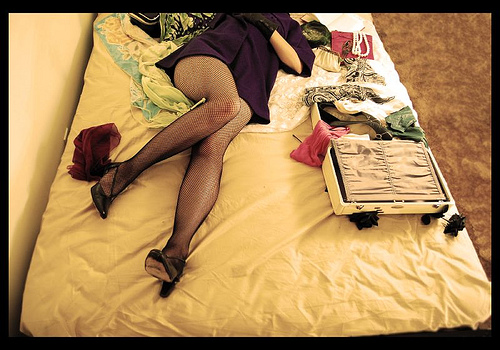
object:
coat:
[155, 12, 315, 125]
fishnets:
[101, 55, 253, 262]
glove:
[235, 13, 281, 39]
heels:
[143, 245, 193, 299]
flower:
[433, 214, 466, 238]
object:
[65, 119, 120, 182]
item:
[385, 105, 425, 144]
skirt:
[322, 100, 392, 141]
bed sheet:
[16, 8, 493, 336]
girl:
[89, 0, 317, 298]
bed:
[15, 11, 498, 344]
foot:
[144, 248, 189, 283]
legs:
[154, 94, 252, 247]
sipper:
[354, 28, 364, 55]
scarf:
[333, 30, 373, 59]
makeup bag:
[302, 43, 345, 73]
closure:
[308, 44, 341, 72]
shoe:
[85, 157, 134, 220]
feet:
[90, 160, 129, 220]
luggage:
[309, 79, 456, 231]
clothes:
[303, 83, 396, 108]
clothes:
[290, 116, 352, 172]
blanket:
[93, 9, 345, 132]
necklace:
[349, 28, 372, 58]